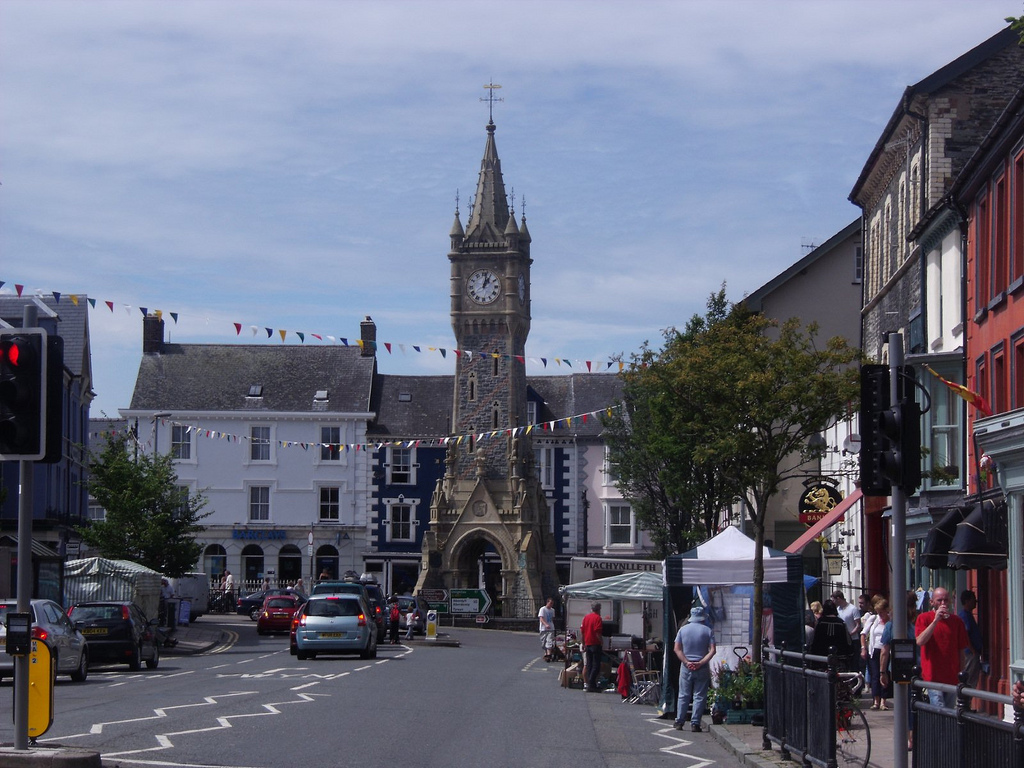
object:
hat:
[681, 607, 715, 628]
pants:
[671, 661, 714, 729]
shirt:
[577, 601, 605, 644]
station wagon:
[68, 593, 163, 679]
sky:
[2, 7, 1012, 371]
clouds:
[550, 5, 817, 103]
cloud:
[25, 35, 337, 217]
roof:
[451, 72, 527, 254]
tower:
[410, 84, 580, 633]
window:
[244, 415, 276, 466]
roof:
[114, 317, 381, 420]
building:
[905, 70, 1019, 765]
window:
[310, 479, 343, 532]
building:
[124, 292, 384, 626]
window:
[164, 418, 199, 465]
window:
[373, 435, 424, 491]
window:
[377, 493, 423, 541]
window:
[600, 441, 641, 495]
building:
[561, 363, 700, 644]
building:
[365, 364, 573, 629]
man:
[555, 604, 638, 703]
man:
[674, 603, 719, 739]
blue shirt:
[672, 622, 719, 668]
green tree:
[686, 284, 855, 726]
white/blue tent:
[650, 516, 809, 705]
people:
[798, 597, 851, 692]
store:
[897, 497, 965, 597]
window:
[599, 501, 643, 554]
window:
[980, 338, 1014, 429]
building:
[843, 9, 1016, 707]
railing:
[755, 646, 842, 761]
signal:
[1, 333, 30, 371]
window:
[240, 473, 274, 529]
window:
[308, 424, 355, 467]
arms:
[692, 625, 720, 668]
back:
[682, 620, 701, 666]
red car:
[250, 587, 315, 638]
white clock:
[461, 262, 505, 307]